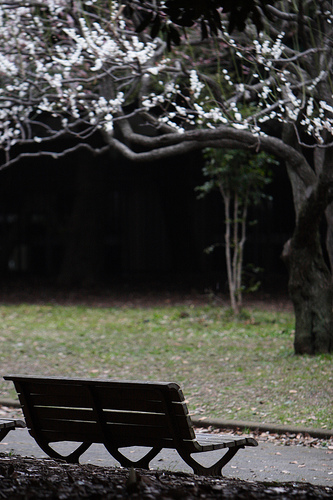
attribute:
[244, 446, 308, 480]
asphalt — black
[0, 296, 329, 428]
grass — small, green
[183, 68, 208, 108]
blossoms — purple, white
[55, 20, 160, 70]
flowers — white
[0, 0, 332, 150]
blooms — white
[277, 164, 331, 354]
trunk — brown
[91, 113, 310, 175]
branches — brown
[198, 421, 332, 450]
leaves — fallen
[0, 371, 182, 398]
slat — wooden, dark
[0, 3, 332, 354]
tree — large, big, young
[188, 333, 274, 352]
leaves — dried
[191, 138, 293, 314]
tree — small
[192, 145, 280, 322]
tree — small, brown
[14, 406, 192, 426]
slat — dark, wooden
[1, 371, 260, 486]
bench — wooden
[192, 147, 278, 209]
leaves — green